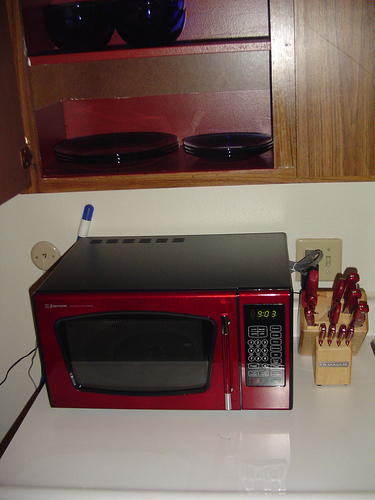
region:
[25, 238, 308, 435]
Bright red microwave sitting on a counter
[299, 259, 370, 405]
Set of red knives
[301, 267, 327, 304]
Red knife handle on counter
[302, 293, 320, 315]
Red knife handle on counter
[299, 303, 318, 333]
Red knife handle on counter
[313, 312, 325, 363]
Red knife handle on counter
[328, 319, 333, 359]
Red knife handle on counter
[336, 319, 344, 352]
Red knife handle on counter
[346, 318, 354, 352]
Red knife handle on counter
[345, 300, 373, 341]
Red knife handle on counter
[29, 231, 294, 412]
Red and black microwave oven on countertop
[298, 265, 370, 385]
Knives in wooden knife holder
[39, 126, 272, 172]
Black plates stacked in cabinet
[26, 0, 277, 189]
Wooden shelf above microwave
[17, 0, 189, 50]
Dishes on the wooden shelf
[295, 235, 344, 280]
Tan light switch to left of microwave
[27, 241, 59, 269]
Tan telephone outlet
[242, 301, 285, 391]
Microwave's control panel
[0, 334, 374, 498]
White countertop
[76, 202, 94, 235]
Blue and white handle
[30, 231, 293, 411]
a red and black microwave oven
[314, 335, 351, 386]
a wooden knife block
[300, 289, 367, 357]
a wooden knife block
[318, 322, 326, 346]
a red knife handle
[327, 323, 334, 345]
a red knife handle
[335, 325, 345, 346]
a red knife handle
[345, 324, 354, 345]
a red knife handle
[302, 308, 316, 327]
a red knife handle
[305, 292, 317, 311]
a red knife handle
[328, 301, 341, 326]
a red knife handle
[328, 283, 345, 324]
Red handle on scissors in block.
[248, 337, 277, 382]
Black buttons on microwave.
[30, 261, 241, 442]
Red microwave on counter top.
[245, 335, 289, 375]
White numbers on buttons on microwave.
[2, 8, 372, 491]
Photo of kitchen settings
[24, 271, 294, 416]
Red and black microwave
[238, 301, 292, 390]
Digital panel on microwave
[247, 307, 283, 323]
9:03 readout on microwave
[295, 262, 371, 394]
Block with assorted knives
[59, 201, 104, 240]
Top of blue and white broom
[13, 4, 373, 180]
Brown wooden kitchen cabinet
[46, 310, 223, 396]
Unlit window of microwave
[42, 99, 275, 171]
Plates sitting in cabinet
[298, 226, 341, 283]
Off grey wall switch